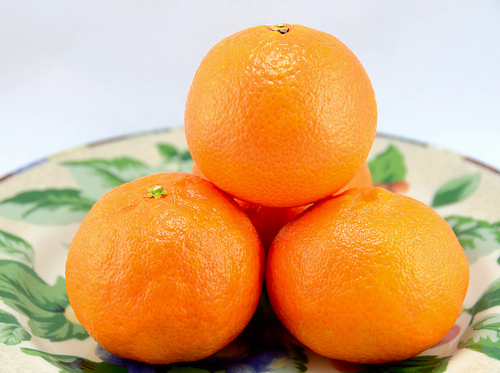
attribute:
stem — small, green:
[147, 183, 170, 198]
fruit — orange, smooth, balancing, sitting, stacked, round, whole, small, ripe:
[184, 22, 380, 208]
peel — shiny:
[218, 39, 352, 189]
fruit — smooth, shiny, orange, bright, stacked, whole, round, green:
[65, 172, 266, 365]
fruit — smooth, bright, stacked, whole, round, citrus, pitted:
[267, 183, 471, 363]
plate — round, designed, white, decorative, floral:
[1, 126, 498, 372]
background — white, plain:
[4, 6, 500, 187]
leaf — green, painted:
[2, 186, 92, 218]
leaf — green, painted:
[370, 143, 406, 188]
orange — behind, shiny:
[191, 162, 373, 254]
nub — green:
[270, 22, 290, 34]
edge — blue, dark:
[3, 126, 500, 182]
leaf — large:
[0, 259, 88, 340]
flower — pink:
[437, 325, 459, 346]